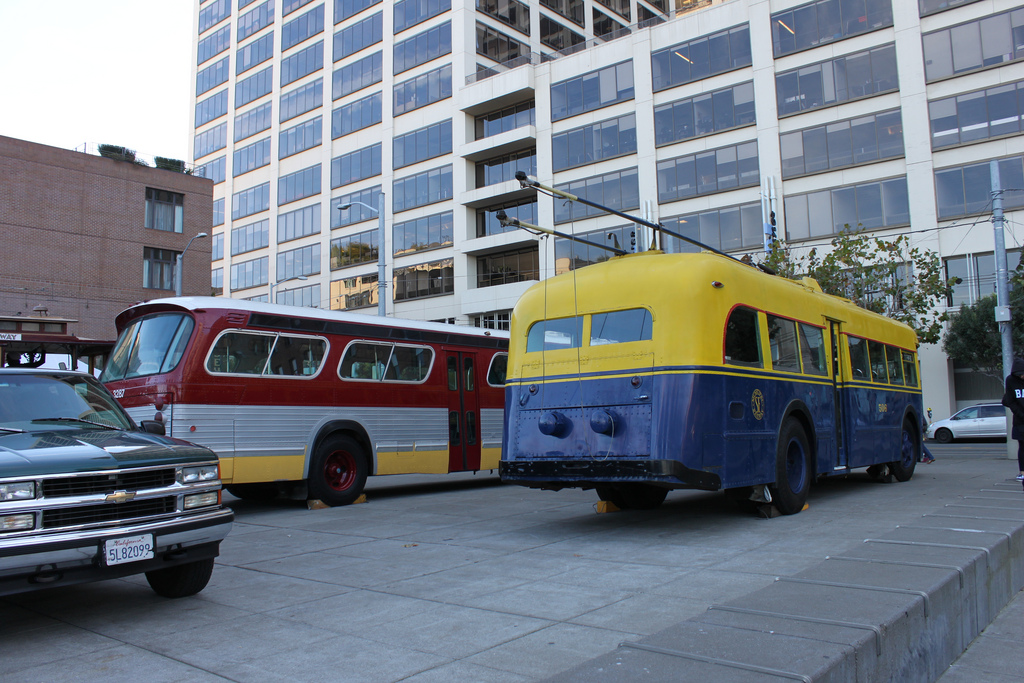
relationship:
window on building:
[525, 63, 637, 114] [172, 11, 991, 444]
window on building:
[647, 33, 777, 103] [172, 11, 991, 444]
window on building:
[754, 5, 907, 60] [172, 11, 991, 444]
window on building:
[773, 41, 929, 136] [172, 11, 991, 444]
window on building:
[756, 168, 937, 260] [172, 11, 991, 444]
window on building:
[540, 105, 667, 172] [172, 11, 991, 444]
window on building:
[644, 79, 785, 153] [172, 11, 991, 444]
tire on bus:
[885, 412, 925, 489] [495, 232, 957, 514]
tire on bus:
[570, 468, 679, 525] [495, 232, 957, 514]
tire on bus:
[770, 403, 817, 525] [495, 232, 957, 514]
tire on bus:
[306, 417, 375, 502] [103, 292, 495, 514]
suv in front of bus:
[10, 345, 246, 618] [495, 232, 957, 514]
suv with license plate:
[10, 345, 246, 618] [92, 520, 169, 578]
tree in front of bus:
[546, 244, 968, 359] [446, 244, 968, 530]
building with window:
[172, 11, 991, 444] [644, 124, 774, 214]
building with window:
[172, 11, 991, 444] [537, 54, 642, 132]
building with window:
[172, 11, 991, 444] [379, 155, 452, 220]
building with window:
[172, 11, 991, 444] [271, 68, 323, 139]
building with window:
[172, 11, 991, 444] [224, 57, 282, 114]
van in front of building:
[915, 396, 1013, 447] [172, 11, 991, 444]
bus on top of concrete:
[495, 232, 957, 514] [3, 440, 1022, 672]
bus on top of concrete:
[88, 264, 496, 512] [3, 440, 1022, 672]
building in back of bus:
[2, 131, 218, 372] [88, 264, 496, 512]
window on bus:
[587, 304, 667, 403] [484, 228, 940, 530]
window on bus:
[512, 304, 589, 403] [484, 228, 940, 530]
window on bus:
[195, 324, 323, 398] [84, 250, 508, 529]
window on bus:
[70, 304, 206, 403] [84, 250, 508, 529]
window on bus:
[323, 324, 442, 398] [84, 250, 508, 529]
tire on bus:
[892, 430, 924, 476] [495, 232, 957, 514]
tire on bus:
[284, 403, 390, 511] [103, 292, 495, 514]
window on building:
[315, 42, 401, 110] [172, 11, 991, 444]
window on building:
[315, 83, 401, 140] [172, 11, 991, 444]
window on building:
[315, 120, 401, 207] [172, 11, 991, 444]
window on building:
[395, 111, 485, 179] [172, 11, 991, 444]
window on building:
[367, 203, 485, 271] [172, 11, 991, 444]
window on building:
[256, 147, 336, 214] [172, 11, 991, 444]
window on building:
[256, 104, 336, 162] [172, 11, 991, 444]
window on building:
[256, 63, 336, 124] [172, 11, 991, 444]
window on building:
[221, 93, 282, 151] [172, 11, 991, 444]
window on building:
[223, 52, 282, 119] [172, 11, 991, 444]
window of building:
[143, 243, 184, 294] [2, 111, 218, 372]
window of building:
[123, 174, 201, 242] [2, 111, 218, 372]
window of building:
[223, 125, 280, 183] [172, 11, 991, 444]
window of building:
[223, 166, 280, 231] [172, 11, 991, 444]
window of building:
[223, 210, 280, 269] [172, 11, 991, 444]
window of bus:
[531, 311, 652, 343] [491, 251, 919, 512]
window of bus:
[586, 299, 664, 348] [491, 251, 919, 512]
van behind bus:
[916, 396, 1014, 448] [496, 237, 1013, 532]